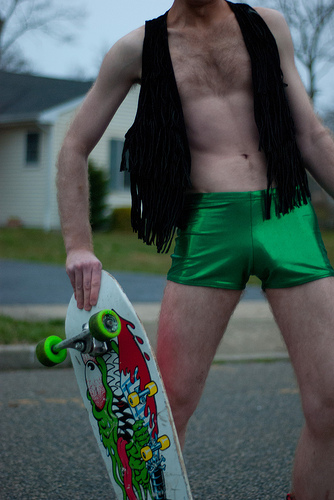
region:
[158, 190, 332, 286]
a green pair of shorts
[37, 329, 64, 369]
a fluorescent green wheel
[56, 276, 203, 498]
a white skateboard with a design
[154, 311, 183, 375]
a red sunburn on a bare leg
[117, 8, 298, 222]
a black fringed vest on a man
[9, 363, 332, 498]
a paved road under a man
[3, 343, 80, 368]
a curb next to a road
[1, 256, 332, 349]
a driveway connecting to the road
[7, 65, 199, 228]
a small house behind a man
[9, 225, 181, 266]
a green lawn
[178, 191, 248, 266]
Person wearing green shorts.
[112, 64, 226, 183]
Black vest has fringe on it.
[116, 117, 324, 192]
Black fringe vest is open.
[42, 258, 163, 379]
Person holding skateboard.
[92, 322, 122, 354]
Skateboard has green wheels.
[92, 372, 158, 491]
Bottom of skateboard is white.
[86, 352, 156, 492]
Green monster on bottom of board.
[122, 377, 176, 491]
Yellow wheels on skateboard pictured on skateboard.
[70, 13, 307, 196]
the man in black vest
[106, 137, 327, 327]
the guy in green shorts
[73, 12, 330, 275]
the guy in green shorts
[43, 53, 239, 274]
the guy in green shorts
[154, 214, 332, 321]
the shorts is green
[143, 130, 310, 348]
the shorts is green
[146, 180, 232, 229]
the shorts is green